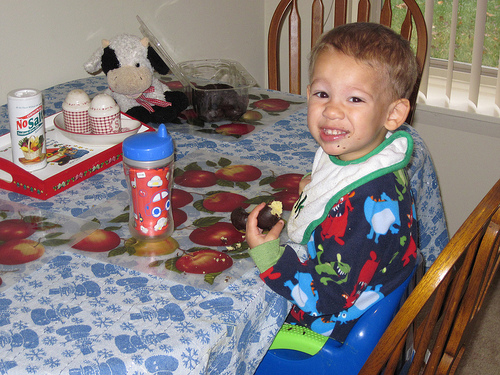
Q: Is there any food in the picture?
A: Yes, there is food.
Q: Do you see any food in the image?
A: Yes, there is food.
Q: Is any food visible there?
A: Yes, there is food.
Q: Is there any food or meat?
A: Yes, there is food.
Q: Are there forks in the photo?
A: No, there are no forks.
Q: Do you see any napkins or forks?
A: No, there are no forks or napkins.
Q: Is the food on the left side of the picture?
A: Yes, the food is on the left of the image.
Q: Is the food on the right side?
A: No, the food is on the left of the image.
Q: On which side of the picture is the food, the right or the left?
A: The food is on the left of the image.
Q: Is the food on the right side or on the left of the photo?
A: The food is on the left of the image.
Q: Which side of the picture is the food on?
A: The food is on the left of the image.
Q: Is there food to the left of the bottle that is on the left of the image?
A: Yes, there is food to the left of the bottle.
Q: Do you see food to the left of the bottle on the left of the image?
A: Yes, there is food to the left of the bottle.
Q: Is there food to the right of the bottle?
A: No, the food is to the left of the bottle.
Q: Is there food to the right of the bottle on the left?
A: No, the food is to the left of the bottle.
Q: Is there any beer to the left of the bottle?
A: No, there is food to the left of the bottle.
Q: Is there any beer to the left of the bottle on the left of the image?
A: No, there is food to the left of the bottle.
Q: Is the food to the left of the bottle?
A: Yes, the food is to the left of the bottle.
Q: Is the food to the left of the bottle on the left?
A: Yes, the food is to the left of the bottle.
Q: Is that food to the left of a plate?
A: No, the food is to the left of the bottle.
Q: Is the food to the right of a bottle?
A: No, the food is to the left of a bottle.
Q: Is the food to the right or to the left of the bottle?
A: The food is to the left of the bottle.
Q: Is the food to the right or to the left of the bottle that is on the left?
A: The food is to the left of the bottle.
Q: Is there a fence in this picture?
A: No, there are no fences.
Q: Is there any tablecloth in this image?
A: Yes, there is a tablecloth.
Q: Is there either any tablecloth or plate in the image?
A: Yes, there is a tablecloth.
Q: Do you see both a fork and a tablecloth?
A: No, there is a tablecloth but no forks.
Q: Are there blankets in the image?
A: No, there are no blankets.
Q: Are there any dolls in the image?
A: Yes, there is a doll.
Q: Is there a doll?
A: Yes, there is a doll.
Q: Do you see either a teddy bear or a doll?
A: Yes, there is a doll.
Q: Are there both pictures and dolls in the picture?
A: No, there is a doll but no pictures.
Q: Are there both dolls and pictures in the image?
A: No, there is a doll but no pictures.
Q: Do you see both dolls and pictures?
A: No, there is a doll but no pictures.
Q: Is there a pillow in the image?
A: No, there are no pillows.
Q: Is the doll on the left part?
A: Yes, the doll is on the left of the image.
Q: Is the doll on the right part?
A: No, the doll is on the left of the image.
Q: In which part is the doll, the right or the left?
A: The doll is on the left of the image.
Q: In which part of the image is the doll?
A: The doll is on the left of the image.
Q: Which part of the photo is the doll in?
A: The doll is on the left of the image.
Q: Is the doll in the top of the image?
A: Yes, the doll is in the top of the image.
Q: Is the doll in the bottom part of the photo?
A: No, the doll is in the top of the image.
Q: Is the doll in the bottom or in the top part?
A: The doll is in the top of the image.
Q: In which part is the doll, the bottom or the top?
A: The doll is in the top of the image.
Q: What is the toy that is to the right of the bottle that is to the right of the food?
A: The toy is a doll.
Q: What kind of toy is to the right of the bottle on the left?
A: The toy is a doll.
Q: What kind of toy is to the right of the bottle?
A: The toy is a doll.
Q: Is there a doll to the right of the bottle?
A: Yes, there is a doll to the right of the bottle.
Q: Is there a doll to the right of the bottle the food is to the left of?
A: Yes, there is a doll to the right of the bottle.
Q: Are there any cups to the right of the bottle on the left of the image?
A: No, there is a doll to the right of the bottle.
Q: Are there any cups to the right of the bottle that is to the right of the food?
A: No, there is a doll to the right of the bottle.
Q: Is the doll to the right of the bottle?
A: Yes, the doll is to the right of the bottle.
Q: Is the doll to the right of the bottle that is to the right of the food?
A: Yes, the doll is to the right of the bottle.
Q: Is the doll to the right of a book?
A: No, the doll is to the right of the bottle.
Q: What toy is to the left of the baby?
A: The toy is a doll.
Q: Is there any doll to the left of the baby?
A: Yes, there is a doll to the left of the baby.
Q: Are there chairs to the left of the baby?
A: No, there is a doll to the left of the baby.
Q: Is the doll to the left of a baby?
A: Yes, the doll is to the left of a baby.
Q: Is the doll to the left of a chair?
A: No, the doll is to the left of a baby.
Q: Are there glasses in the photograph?
A: No, there are no glasses.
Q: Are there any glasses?
A: No, there are no glasses.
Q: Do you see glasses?
A: No, there are no glasses.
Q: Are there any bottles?
A: Yes, there is a bottle.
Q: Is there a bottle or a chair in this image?
A: Yes, there is a bottle.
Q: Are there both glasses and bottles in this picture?
A: No, there is a bottle but no glasses.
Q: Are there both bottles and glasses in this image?
A: No, there is a bottle but no glasses.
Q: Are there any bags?
A: No, there are no bags.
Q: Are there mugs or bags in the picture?
A: No, there are no bags or mugs.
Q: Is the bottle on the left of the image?
A: Yes, the bottle is on the left of the image.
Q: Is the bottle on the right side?
A: No, the bottle is on the left of the image.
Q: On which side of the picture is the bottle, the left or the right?
A: The bottle is on the left of the image.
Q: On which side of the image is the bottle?
A: The bottle is on the left of the image.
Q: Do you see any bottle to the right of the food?
A: Yes, there is a bottle to the right of the food.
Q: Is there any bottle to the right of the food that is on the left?
A: Yes, there is a bottle to the right of the food.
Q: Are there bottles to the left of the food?
A: No, the bottle is to the right of the food.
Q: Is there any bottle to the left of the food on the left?
A: No, the bottle is to the right of the food.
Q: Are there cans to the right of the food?
A: No, there is a bottle to the right of the food.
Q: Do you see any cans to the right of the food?
A: No, there is a bottle to the right of the food.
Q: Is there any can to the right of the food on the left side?
A: No, there is a bottle to the right of the food.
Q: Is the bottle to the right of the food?
A: Yes, the bottle is to the right of the food.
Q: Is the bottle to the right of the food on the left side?
A: Yes, the bottle is to the right of the food.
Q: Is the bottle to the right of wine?
A: No, the bottle is to the right of the food.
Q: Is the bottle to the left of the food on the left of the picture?
A: No, the bottle is to the right of the food.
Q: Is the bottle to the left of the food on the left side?
A: No, the bottle is to the right of the food.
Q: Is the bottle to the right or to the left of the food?
A: The bottle is to the right of the food.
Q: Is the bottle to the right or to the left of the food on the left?
A: The bottle is to the right of the food.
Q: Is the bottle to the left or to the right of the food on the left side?
A: The bottle is to the right of the food.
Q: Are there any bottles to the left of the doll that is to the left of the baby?
A: Yes, there is a bottle to the left of the doll.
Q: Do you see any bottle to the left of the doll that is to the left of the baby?
A: Yes, there is a bottle to the left of the doll.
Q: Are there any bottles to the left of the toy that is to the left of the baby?
A: Yes, there is a bottle to the left of the doll.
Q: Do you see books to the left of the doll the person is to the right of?
A: No, there is a bottle to the left of the doll.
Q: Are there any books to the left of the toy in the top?
A: No, there is a bottle to the left of the doll.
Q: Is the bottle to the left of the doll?
A: Yes, the bottle is to the left of the doll.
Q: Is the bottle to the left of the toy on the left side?
A: Yes, the bottle is to the left of the doll.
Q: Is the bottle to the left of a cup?
A: No, the bottle is to the left of the doll.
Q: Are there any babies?
A: Yes, there is a baby.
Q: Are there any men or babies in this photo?
A: Yes, there is a baby.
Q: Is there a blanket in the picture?
A: No, there are no blankets.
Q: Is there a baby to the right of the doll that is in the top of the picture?
A: Yes, there is a baby to the right of the doll.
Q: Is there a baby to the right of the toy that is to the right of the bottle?
A: Yes, there is a baby to the right of the doll.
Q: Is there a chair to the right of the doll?
A: No, there is a baby to the right of the doll.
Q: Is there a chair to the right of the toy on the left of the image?
A: No, there is a baby to the right of the doll.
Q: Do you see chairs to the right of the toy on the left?
A: No, there is a baby to the right of the doll.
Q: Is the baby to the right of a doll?
A: Yes, the baby is to the right of a doll.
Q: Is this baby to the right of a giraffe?
A: No, the baby is to the right of a doll.